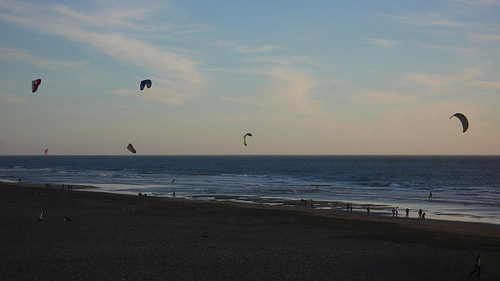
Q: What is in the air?
A: Kites.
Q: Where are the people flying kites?
A: At the beach.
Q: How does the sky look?
A: Partly cloudy.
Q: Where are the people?
A: On the beach.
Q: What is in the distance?
A: The ocean.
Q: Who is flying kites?
A: The people on the beach.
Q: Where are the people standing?
A: On the beach.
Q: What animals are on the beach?
A: Birds.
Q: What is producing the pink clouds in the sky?
A: The sunset.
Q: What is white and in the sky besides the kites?
A: Clouds.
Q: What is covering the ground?
A: Sand.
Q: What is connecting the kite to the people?
A: String.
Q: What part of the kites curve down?
A: The outside.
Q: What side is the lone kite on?
A: The right.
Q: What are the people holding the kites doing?
A: Para surfing.